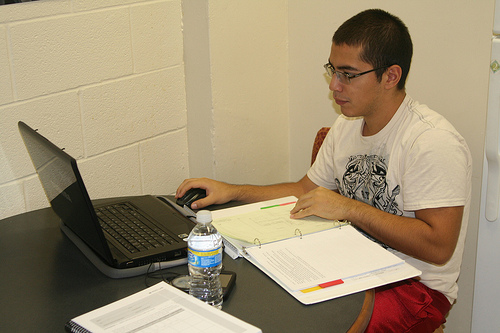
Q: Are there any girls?
A: No, there are no girls.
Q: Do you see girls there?
A: No, there are no girls.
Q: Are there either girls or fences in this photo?
A: No, there are no girls or fences.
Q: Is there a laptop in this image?
A: Yes, there is a laptop.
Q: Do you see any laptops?
A: Yes, there is a laptop.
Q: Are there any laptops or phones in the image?
A: Yes, there is a laptop.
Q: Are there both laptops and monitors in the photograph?
A: No, there is a laptop but no monitors.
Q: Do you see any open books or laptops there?
A: Yes, there is an open laptop.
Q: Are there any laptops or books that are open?
A: Yes, the laptop is open.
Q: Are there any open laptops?
A: Yes, there is an open laptop.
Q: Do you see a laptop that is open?
A: Yes, there is an open laptop.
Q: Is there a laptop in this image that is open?
A: Yes, there is a laptop that is open.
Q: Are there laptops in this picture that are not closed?
A: Yes, there is a open laptop.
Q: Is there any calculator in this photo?
A: No, there are no calculators.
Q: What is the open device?
A: The device is a laptop.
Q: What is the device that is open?
A: The device is a laptop.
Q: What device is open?
A: The device is a laptop.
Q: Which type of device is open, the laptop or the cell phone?
A: The laptop is open.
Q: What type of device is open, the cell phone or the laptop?
A: The laptop is open.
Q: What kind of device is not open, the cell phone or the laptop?
A: The cell phone is not open.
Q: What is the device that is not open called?
A: The device is a cell phone.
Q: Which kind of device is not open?
A: The device is a cell phone.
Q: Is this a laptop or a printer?
A: This is a laptop.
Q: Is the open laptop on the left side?
A: Yes, the laptop is on the left of the image.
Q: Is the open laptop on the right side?
A: No, the laptop computer is on the left of the image.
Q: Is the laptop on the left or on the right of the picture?
A: The laptop is on the left of the image.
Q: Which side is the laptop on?
A: The laptop is on the left of the image.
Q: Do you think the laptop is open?
A: Yes, the laptop is open.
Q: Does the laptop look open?
A: Yes, the laptop is open.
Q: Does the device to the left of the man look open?
A: Yes, the laptop is open.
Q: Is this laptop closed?
A: No, the laptop is open.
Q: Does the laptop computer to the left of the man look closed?
A: No, the laptop is open.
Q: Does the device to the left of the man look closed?
A: No, the laptop is open.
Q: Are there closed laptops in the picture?
A: No, there is a laptop but it is open.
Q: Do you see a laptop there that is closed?
A: No, there is a laptop but it is open.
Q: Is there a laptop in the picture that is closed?
A: No, there is a laptop but it is open.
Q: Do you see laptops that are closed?
A: No, there is a laptop but it is open.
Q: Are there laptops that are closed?
A: No, there is a laptop but it is open.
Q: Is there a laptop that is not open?
A: No, there is a laptop but it is open.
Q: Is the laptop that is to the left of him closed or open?
A: The laptop is open.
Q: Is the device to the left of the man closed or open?
A: The laptop is open.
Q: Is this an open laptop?
A: Yes, this is an open laptop.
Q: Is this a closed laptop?
A: No, this is an open laptop.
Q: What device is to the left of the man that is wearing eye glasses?
A: The device is a laptop.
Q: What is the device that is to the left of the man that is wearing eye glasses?
A: The device is a laptop.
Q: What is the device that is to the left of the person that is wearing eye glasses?
A: The device is a laptop.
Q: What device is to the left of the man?
A: The device is a laptop.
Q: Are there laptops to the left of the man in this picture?
A: Yes, there is a laptop to the left of the man.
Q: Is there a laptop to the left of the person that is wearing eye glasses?
A: Yes, there is a laptop to the left of the man.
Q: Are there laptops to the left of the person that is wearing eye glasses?
A: Yes, there is a laptop to the left of the man.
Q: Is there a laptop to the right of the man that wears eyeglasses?
A: No, the laptop is to the left of the man.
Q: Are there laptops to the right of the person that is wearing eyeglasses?
A: No, the laptop is to the left of the man.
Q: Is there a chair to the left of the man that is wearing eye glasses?
A: No, there is a laptop to the left of the man.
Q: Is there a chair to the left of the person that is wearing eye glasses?
A: No, there is a laptop to the left of the man.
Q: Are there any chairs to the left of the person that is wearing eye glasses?
A: No, there is a laptop to the left of the man.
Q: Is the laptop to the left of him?
A: Yes, the laptop is to the left of the man.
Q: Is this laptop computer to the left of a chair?
A: No, the laptop computer is to the left of the man.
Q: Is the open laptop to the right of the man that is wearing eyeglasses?
A: No, the laptop is to the left of the man.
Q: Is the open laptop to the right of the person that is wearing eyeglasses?
A: No, the laptop is to the left of the man.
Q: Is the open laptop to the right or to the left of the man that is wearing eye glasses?
A: The laptop is to the left of the man.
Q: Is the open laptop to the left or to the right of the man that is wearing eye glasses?
A: The laptop is to the left of the man.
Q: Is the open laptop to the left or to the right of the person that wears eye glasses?
A: The laptop is to the left of the man.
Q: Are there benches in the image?
A: No, there are no benches.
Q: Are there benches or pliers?
A: No, there are no benches or pliers.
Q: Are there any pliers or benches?
A: No, there are no benches or pliers.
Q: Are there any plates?
A: No, there are no plates.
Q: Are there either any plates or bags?
A: No, there are no plates or bags.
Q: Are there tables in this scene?
A: Yes, there is a table.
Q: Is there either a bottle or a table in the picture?
A: Yes, there is a table.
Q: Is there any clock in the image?
A: No, there are no clocks.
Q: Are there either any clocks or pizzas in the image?
A: No, there are no clocks or pizzas.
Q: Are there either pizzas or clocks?
A: No, there are no clocks or pizzas.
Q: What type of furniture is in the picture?
A: The furniture is a table.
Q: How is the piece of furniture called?
A: The piece of furniture is a table.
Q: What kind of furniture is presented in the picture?
A: The furniture is a table.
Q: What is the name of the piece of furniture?
A: The piece of furniture is a table.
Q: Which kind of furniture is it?
A: The piece of furniture is a table.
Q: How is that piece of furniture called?
A: This is a table.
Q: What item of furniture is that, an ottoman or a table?
A: This is a table.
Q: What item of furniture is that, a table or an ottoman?
A: This is a table.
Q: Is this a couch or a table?
A: This is a table.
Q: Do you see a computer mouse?
A: Yes, there is a computer mouse.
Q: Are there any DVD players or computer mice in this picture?
A: Yes, there is a computer mouse.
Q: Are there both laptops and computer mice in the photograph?
A: Yes, there are both a computer mouse and a laptop.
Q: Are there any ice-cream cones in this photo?
A: No, there are no ice-cream cones.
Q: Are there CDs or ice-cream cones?
A: No, there are no ice-cream cones or cds.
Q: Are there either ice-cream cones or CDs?
A: No, there are no ice-cream cones or cds.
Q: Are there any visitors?
A: No, there are no visitors.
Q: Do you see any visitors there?
A: No, there are no visitors.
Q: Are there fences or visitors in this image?
A: No, there are no visitors or fences.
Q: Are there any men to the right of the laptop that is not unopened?
A: Yes, there is a man to the right of the laptop.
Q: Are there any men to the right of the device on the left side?
A: Yes, there is a man to the right of the laptop.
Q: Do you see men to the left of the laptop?
A: No, the man is to the right of the laptop.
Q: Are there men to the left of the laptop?
A: No, the man is to the right of the laptop.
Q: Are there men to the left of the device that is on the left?
A: No, the man is to the right of the laptop.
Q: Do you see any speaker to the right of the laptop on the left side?
A: No, there is a man to the right of the laptop.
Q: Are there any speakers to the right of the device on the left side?
A: No, there is a man to the right of the laptop.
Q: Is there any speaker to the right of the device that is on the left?
A: No, there is a man to the right of the laptop.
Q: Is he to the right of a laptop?
A: Yes, the man is to the right of a laptop.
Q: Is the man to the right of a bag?
A: No, the man is to the right of a laptop.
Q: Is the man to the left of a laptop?
A: No, the man is to the right of a laptop.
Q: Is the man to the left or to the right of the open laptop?
A: The man is to the right of the laptop.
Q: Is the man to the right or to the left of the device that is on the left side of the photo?
A: The man is to the right of the laptop.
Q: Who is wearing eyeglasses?
A: The man is wearing eyeglasses.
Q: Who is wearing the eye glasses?
A: The man is wearing eyeglasses.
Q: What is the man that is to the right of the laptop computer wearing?
A: The man is wearing eyeglasses.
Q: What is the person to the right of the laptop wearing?
A: The man is wearing eyeglasses.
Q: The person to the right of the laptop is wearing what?
A: The man is wearing eyeglasses.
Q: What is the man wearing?
A: The man is wearing eyeglasses.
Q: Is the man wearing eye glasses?
A: Yes, the man is wearing eye glasses.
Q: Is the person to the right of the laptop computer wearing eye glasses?
A: Yes, the man is wearing eye glasses.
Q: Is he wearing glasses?
A: No, the man is wearing eye glasses.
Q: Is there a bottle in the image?
A: Yes, there is a bottle.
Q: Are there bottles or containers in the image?
A: Yes, there is a bottle.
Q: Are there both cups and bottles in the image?
A: No, there is a bottle but no cups.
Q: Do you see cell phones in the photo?
A: Yes, there is a cell phone.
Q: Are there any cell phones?
A: Yes, there is a cell phone.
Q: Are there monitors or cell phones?
A: Yes, there is a cell phone.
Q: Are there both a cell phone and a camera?
A: No, there is a cell phone but no cameras.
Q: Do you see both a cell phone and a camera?
A: No, there is a cell phone but no cameras.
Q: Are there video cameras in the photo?
A: No, there are no video cameras.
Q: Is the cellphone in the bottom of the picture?
A: Yes, the cellphone is in the bottom of the image.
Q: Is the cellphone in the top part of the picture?
A: No, the cellphone is in the bottom of the image.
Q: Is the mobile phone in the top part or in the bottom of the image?
A: The mobile phone is in the bottom of the image.